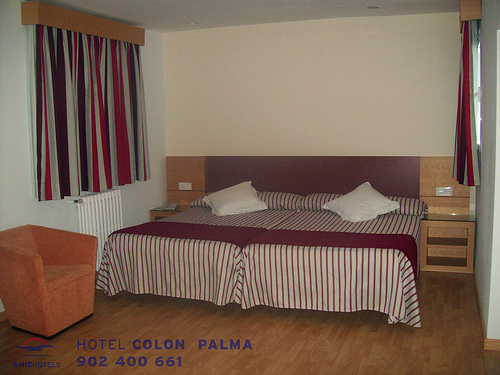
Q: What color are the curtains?
A: Red, brown and white.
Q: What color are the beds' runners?
A: Maroon.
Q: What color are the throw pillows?
A: White.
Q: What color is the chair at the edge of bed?
A: Red.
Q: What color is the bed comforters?
A: White and red.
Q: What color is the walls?
A: White.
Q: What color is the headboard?
A: Brown.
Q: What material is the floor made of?
A: Wood.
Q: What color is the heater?
A: White.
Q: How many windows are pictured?
A: Two.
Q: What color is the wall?
A: White.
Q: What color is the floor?
A: Brown.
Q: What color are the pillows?
A: White.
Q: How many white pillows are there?
A: 2.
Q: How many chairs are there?
A: One.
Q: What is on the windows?
A: Curtains.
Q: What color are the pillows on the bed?
A: White.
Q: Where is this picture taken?
A: A bedroom.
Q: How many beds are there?
A: 2.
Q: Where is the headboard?
A: Behind the bed.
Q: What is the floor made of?
A: Wood.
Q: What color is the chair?
A: Orange.